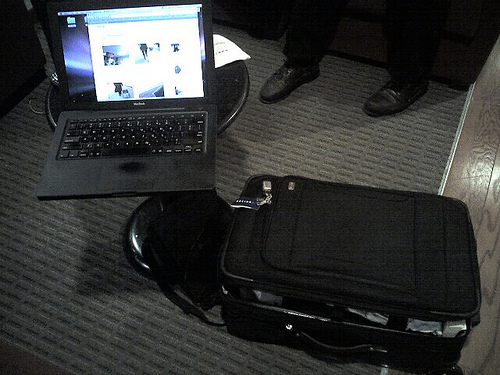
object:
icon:
[66, 17, 77, 28]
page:
[86, 4, 203, 102]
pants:
[278, 0, 433, 70]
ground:
[8, 29, 485, 366]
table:
[44, 24, 251, 147]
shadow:
[73, 134, 276, 300]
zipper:
[257, 194, 273, 206]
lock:
[261, 181, 272, 201]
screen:
[46, 4, 214, 110]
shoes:
[260, 59, 322, 105]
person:
[256, 3, 434, 116]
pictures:
[100, 44, 129, 67]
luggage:
[222, 173, 480, 370]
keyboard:
[57, 109, 210, 161]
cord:
[28, 99, 45, 115]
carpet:
[0, 97, 454, 375]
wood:
[468, 130, 496, 206]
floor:
[5, 89, 496, 364]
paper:
[213, 34, 251, 70]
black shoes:
[362, 77, 430, 118]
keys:
[93, 142, 105, 148]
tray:
[44, 29, 248, 145]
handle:
[285, 326, 385, 365]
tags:
[231, 197, 261, 211]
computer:
[40, 3, 219, 200]